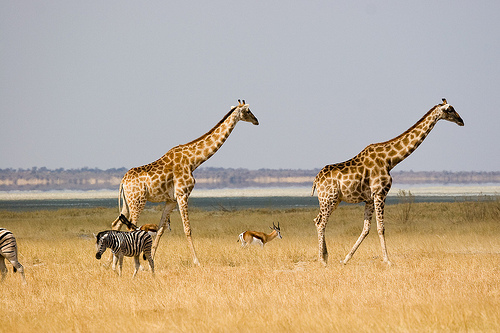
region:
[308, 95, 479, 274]
giraffe in the forest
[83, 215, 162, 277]
zebra in the forest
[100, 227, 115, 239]
mane in the zebra's neck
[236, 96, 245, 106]
horn in the zebra's head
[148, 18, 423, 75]
a clear sky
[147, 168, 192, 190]
brown polygons on a cream/tan background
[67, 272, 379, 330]
brown color grass on the ground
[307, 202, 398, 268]
legs of the giraffe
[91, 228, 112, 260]
head of the zebra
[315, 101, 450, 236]
giraffe has long neck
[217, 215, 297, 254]
gazelle is behind giraffe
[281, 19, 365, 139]
grey and hazy sky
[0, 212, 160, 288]
zebras next to giraffes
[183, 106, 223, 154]
giraffe has brown mane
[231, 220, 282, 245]
a gazelle on the savannah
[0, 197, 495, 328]
savannah grasses surrounding animals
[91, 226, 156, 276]
a zebra in front of a giraffe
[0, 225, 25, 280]
the hind quarters of a zebra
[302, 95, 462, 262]
a giraffe walking in front of another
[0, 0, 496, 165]
a pale grey sky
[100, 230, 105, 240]
the ear of a zebra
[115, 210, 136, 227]
black hair at the end of a giraffe's tail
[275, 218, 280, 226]
the horn of a gazelle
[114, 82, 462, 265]
two giraffes walking together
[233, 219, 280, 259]
deer walking between the giraffes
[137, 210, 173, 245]
deer behind the giraffe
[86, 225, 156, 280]
zebra in front of the giraffe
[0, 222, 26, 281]
partially obscured zebra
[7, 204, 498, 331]
dried grass pasture animals are in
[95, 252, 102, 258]
black nose of the zebra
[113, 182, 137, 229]
swinging tale of the giraffe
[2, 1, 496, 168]
blue gray sky above the pasture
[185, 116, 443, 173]
long necks of the giraffes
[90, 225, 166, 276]
black and white zebra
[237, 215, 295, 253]
brown and black gazelle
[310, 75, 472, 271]
tall brown giraffe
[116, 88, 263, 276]
tall brown giraffe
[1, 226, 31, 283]
back of black and white zebra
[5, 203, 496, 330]
brown grass field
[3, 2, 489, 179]
gray smoggy sky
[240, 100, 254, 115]
white giraffe ear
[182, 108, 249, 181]
long giraffe neck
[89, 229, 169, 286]
zebra in a field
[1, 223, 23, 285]
zebra in a field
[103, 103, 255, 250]
giraffe in a field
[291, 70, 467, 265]
giraffe in a field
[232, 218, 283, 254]
antelope in a field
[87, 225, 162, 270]
zebra walking in a field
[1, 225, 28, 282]
zebra standing in a field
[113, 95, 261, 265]
giraffe walking in a field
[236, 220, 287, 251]
antelope walking in a field